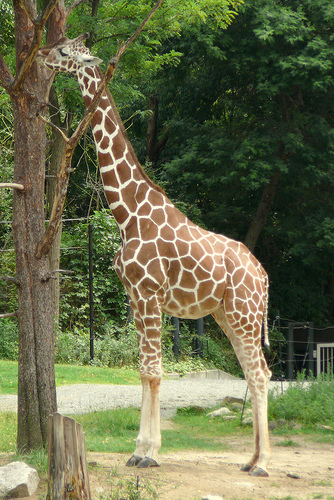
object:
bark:
[27, 311, 41, 375]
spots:
[177, 253, 198, 275]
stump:
[43, 410, 90, 500]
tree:
[0, 0, 164, 458]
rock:
[0, 458, 40, 500]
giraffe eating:
[0, 0, 272, 478]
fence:
[315, 340, 334, 382]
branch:
[33, 0, 161, 259]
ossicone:
[68, 30, 91, 50]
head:
[34, 30, 103, 78]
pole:
[87, 221, 95, 366]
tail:
[262, 266, 270, 370]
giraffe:
[34, 30, 271, 479]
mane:
[95, 64, 165, 198]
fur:
[175, 242, 226, 290]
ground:
[0, 358, 334, 500]